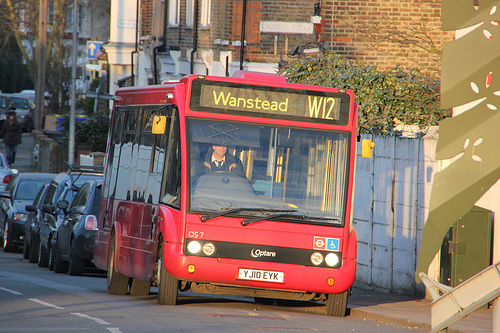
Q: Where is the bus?
A: On the street.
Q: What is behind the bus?
A: Cars.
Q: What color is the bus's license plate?
A: White.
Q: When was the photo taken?
A: During the day.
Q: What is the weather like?
A: Sunny.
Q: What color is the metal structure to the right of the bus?
A: Green.